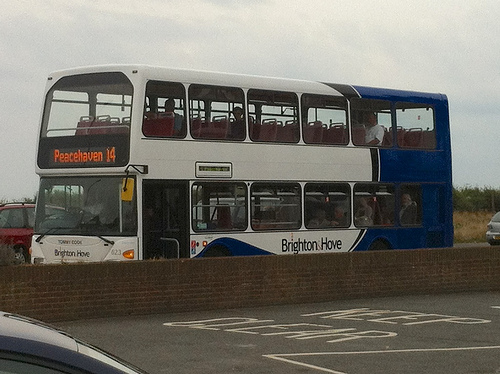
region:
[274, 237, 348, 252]
Name on side of bus.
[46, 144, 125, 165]
Marquee displaying destination and number of route on front of bus.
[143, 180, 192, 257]
Doors to enter bus.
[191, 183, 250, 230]
First window on first level of bus.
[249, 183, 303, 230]
Second window on first level of bus.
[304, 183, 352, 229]
Third window on first level of bus.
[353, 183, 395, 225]
Fourth window on first level of bus.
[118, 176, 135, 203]
Yellow side view mirror on bus.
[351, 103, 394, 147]
Man sitting on second level of bus in white t-shirt.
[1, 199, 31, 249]
Red car on left side of bus.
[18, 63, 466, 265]
This is a bus.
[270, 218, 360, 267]
This says Brighton Hove.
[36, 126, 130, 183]
This says Peacehaven 14.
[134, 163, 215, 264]
This is a door.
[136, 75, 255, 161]
This is a window.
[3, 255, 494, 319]
This is a wall.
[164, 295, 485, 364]
This says KEEP CLEAR.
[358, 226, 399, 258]
This is half a tire.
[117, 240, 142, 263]
This is a headlight.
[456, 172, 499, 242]
This is vegetation.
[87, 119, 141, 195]
bus is number 14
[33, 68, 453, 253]
it is a double deck bus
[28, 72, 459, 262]
bus is white and blue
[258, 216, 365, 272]
Brighton hove is written on the bus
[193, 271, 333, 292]
the wall is made of bricks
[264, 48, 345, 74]
the weather is cloudy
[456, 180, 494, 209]
the trees are green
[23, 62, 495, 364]
it is a daytime scene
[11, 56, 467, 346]
it is an outdoor scene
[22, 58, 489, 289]
the bus is only one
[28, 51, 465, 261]
White and blue double decker bus on highway.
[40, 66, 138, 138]
Front window on top portion of bus.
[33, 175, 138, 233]
Front window on bottom portion of bus.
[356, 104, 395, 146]
Man sitting in back of top portion of bus.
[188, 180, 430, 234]
Windows on side of bottom portion of bus.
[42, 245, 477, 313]
Red brick wall next to highway.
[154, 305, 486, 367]
White writing on parking lot.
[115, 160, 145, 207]
Side view mirror of bus.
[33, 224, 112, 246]
Windshield wipers on front window.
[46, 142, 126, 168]
Destination in front of top portion of bus.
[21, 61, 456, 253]
Double decker bus.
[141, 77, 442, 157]
Windows on the bus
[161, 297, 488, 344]
Writing on the pavement.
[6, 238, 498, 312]
Median in the road.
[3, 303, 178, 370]
Hood of a car.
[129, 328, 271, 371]
Pavement is asphalt.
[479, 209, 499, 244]
Back of a car.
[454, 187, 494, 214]
Trees are green with leaves.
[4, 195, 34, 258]
Car is behind bus.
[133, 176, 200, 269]
Bus has a door.